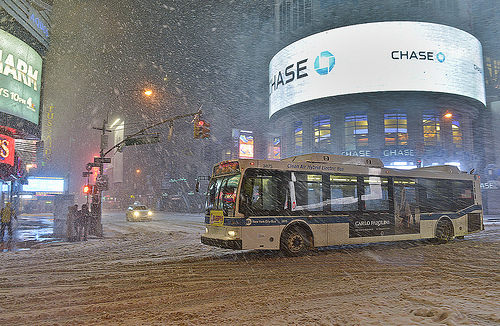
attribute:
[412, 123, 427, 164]
building — large, round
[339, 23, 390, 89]
sign — lighted, advertisement, chase, blue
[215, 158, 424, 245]
bus — white, night, blue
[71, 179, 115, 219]
pole — metal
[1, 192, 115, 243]
people — standing, waiting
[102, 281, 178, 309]
streets — covered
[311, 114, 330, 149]
windows — lit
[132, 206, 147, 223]
car — single, driving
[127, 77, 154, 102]
light — red, yellow, on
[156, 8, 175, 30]
snow — covered, brown